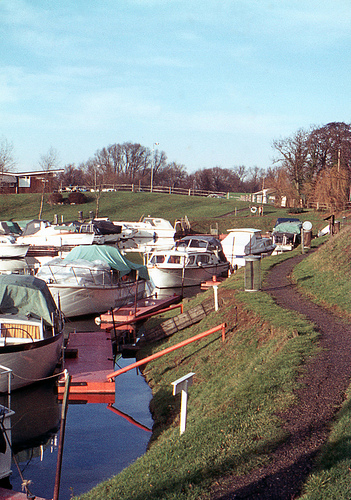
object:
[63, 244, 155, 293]
cover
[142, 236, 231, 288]
boat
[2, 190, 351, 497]
grass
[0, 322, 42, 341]
curtains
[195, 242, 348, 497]
street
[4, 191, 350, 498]
ground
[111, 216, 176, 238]
boat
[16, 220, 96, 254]
boat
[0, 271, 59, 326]
covering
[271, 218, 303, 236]
covering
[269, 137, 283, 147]
leaves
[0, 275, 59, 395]
boats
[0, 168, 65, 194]
shack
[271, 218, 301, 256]
boat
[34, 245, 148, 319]
boat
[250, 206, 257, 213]
sign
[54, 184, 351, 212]
fence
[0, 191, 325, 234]
hill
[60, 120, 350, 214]
tree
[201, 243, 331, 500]
path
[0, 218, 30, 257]
boats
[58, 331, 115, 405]
dock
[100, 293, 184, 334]
dock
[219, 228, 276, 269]
white boat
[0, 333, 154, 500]
water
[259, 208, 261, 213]
jacket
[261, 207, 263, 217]
pole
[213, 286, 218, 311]
pole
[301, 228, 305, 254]
pole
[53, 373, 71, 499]
pole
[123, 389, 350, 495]
shadow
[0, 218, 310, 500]
harbor